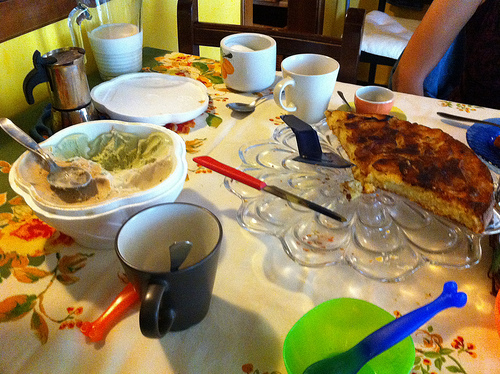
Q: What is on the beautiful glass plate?
A: Food.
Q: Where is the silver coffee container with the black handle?
A: On the table.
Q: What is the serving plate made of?
A: Glass.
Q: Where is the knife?
A: On the plate.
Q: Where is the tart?
A: On the plate.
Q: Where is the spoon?
A: In a bowl.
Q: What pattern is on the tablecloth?
A: Floral.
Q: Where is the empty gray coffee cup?
A: Beside the bowl.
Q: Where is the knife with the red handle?
A: On the plate.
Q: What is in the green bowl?
A: A blue spoon.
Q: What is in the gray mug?
A: A silver spoon.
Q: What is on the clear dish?
A: A pastry.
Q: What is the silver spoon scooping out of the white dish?
A: Ice Cream.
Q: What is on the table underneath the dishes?
A: A table cloth.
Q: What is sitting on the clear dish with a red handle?
A: A knife.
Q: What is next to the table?
A: A brown chair.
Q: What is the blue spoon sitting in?
A: A green bowel.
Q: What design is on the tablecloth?
A: A floral design.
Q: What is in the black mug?
A: It is empty.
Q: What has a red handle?
A: The knife.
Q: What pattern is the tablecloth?
A: Floral.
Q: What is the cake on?
A: Platter.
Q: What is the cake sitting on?
A: A stand.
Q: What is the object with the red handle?
A: A knife.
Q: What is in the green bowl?
A: A blue utensil.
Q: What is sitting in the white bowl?
A: A spoon.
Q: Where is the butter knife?
A: On the cake plate.